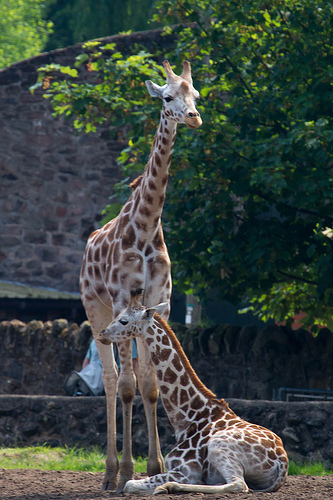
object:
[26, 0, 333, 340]
tree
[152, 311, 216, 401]
mane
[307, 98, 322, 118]
ground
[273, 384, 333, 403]
railing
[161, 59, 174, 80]
horn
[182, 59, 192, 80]
horn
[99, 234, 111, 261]
spots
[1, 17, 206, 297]
wall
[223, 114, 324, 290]
leaves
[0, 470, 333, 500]
ground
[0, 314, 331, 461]
fence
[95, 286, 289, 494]
giraffe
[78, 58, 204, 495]
giraffe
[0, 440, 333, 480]
grass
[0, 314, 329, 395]
wall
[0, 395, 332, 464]
wall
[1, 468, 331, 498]
dirt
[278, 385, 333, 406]
metal pipes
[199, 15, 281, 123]
leaves